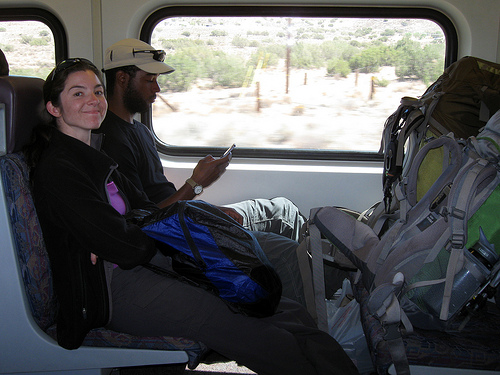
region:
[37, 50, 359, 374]
Woman is smiling for the camera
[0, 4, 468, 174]
Windows behind the people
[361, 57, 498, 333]
Large backpacks are in seats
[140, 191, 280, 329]
The bag is black and blue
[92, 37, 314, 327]
The man is on his phone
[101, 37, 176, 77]
On the persons hat is sunglasses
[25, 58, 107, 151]
sunglasses are on the woman's head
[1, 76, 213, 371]
The seats are cushioned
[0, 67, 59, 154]
Head rests are brown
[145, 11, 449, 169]
The ground outside is covered in sand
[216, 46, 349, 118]
window on side of bus.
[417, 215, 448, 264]
gray backpack in the seat.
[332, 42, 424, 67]
bushes outside of window.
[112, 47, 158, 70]
hat on man's head.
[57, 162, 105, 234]
black shirt on woman.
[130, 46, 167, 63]
sunglasses on man's head.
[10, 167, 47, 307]
cloth pattern on seat.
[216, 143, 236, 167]
cell phone in man's hand.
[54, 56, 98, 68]
sunglasses on woman's head.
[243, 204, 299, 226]
blue jeans on man.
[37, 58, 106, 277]
this is a lady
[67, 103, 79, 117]
the lady has light skin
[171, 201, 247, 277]
this is a bag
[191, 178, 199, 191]
this is a wrist watch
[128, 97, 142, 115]
the man has beards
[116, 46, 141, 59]
this is a cap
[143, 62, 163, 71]
the cap is white in color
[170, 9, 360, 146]
this is a window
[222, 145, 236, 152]
this is a phone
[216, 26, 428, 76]
these are trees outside the vehicle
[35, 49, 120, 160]
women smiling at the cameraman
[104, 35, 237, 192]
man in hat looking at phone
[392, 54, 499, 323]
2 hiking backpacks sitting on a the seat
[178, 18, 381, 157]
desert landscape with cactus, bushes and dirt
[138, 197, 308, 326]
blue and black satchel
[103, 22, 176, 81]
black sunglasses on a tan hat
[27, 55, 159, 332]
woman wearing a black jacket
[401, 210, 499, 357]
water bottle in the side of the pack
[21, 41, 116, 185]
black sunglasses on the woman's head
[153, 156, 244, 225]
man wearing a tan watch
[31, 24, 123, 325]
A smiling woman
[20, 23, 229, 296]
Two people traveling by train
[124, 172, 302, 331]
A black and blue bag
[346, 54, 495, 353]
A silver and green backpack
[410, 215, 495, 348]
A water bottle on a backpack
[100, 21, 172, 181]
A man wearing a hat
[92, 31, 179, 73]
Sun glasses on a hat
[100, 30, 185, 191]
A man wearing a black shirt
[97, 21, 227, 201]
A man wearing a watch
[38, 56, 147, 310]
A woman wearing a black jacket